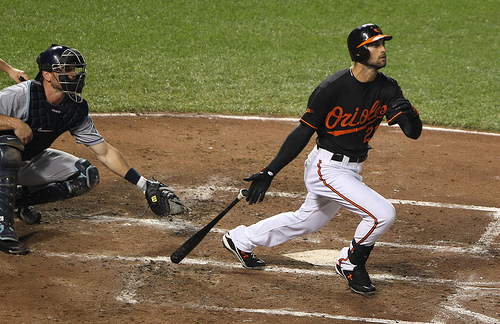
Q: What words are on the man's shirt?
A: Orioles.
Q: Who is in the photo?
A: Two men.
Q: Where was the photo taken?
A: At a baseball game.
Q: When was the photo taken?
A: Daytime.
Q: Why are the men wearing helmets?
A: For safety.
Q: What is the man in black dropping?
A: His bat.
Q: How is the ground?
A: Brown dirt with white stripes.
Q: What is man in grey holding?
A: A baseball glove.